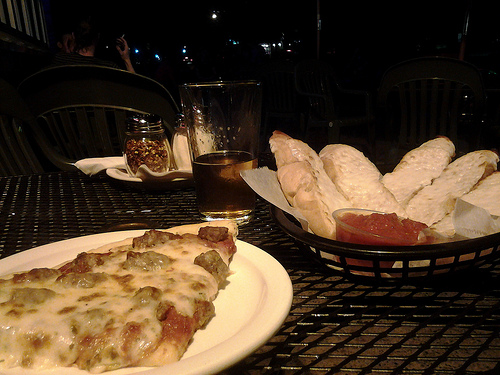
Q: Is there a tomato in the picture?
A: No, there are no tomatoes.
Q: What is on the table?
A: The spices are on the table.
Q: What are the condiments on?
A: The condiments are on the table.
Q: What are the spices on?
A: The condiments are on the table.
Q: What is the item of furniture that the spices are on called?
A: The piece of furniture is a table.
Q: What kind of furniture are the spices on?
A: The spices are on the table.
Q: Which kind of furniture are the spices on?
A: The spices are on the table.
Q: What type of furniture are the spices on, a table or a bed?
A: The spices are on a table.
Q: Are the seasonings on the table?
A: Yes, the seasonings are on the table.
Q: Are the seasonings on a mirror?
A: No, the seasonings are on the table.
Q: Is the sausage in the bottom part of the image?
A: Yes, the sausage is in the bottom of the image.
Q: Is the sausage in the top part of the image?
A: No, the sausage is in the bottom of the image.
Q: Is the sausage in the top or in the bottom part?
A: The sausage is in the bottom of the image.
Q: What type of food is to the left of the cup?
A: The food is a sausage.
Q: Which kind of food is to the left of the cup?
A: The food is a sausage.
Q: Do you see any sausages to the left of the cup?
A: Yes, there is a sausage to the left of the cup.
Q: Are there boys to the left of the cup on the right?
A: No, there is a sausage to the left of the cup.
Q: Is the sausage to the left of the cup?
A: Yes, the sausage is to the left of the cup.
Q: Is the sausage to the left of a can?
A: No, the sausage is to the left of the cup.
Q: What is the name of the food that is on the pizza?
A: The food is a sausage.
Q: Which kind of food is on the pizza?
A: The food is a sausage.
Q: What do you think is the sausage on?
A: The sausage is on the pizza.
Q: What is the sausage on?
A: The sausage is on the pizza.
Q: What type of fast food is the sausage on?
A: The sausage is on the pizza.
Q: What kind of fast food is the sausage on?
A: The sausage is on the pizza.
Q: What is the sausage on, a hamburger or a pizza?
A: The sausage is on a pizza.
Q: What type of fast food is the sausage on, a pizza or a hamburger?
A: The sausage is on a pizza.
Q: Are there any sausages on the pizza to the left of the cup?
A: Yes, there is a sausage on the pizza.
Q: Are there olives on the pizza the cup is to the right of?
A: No, there is a sausage on the pizza.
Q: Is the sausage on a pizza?
A: Yes, the sausage is on a pizza.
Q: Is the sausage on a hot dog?
A: No, the sausage is on a pizza.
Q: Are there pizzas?
A: Yes, there is a pizza.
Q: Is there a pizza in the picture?
A: Yes, there is a pizza.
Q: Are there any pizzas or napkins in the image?
A: Yes, there is a pizza.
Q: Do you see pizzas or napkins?
A: Yes, there is a pizza.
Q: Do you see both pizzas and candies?
A: No, there is a pizza but no candies.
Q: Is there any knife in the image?
A: No, there are no knives.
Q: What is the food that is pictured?
A: The food is a pizza.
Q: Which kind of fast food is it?
A: The food is a pizza.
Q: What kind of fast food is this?
A: This is a pizza.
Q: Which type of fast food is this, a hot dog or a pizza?
A: This is a pizza.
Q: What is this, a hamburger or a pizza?
A: This is a pizza.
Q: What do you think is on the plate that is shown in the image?
A: The pizza is on the plate.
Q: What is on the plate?
A: The pizza is on the plate.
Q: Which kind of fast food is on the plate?
A: The food is a pizza.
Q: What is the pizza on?
A: The pizza is on the plate.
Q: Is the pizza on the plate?
A: Yes, the pizza is on the plate.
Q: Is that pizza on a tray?
A: No, the pizza is on the plate.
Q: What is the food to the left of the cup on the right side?
A: The food is a pizza.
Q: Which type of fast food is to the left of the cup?
A: The food is a pizza.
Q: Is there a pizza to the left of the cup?
A: Yes, there is a pizza to the left of the cup.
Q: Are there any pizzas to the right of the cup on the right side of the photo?
A: No, the pizza is to the left of the cup.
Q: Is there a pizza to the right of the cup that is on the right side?
A: No, the pizza is to the left of the cup.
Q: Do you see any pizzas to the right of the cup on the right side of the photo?
A: No, the pizza is to the left of the cup.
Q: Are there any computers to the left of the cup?
A: No, there is a pizza to the left of the cup.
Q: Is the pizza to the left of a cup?
A: Yes, the pizza is to the left of a cup.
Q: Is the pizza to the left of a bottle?
A: No, the pizza is to the left of a cup.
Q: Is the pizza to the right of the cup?
A: No, the pizza is to the left of the cup.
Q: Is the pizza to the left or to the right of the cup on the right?
A: The pizza is to the left of the cup.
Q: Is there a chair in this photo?
A: Yes, there is a chair.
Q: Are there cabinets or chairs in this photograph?
A: Yes, there is a chair.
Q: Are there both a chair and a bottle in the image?
A: No, there is a chair but no bottles.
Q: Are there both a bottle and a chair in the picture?
A: No, there is a chair but no bottles.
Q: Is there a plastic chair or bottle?
A: Yes, there is a plastic chair.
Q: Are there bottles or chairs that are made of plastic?
A: Yes, the chair is made of plastic.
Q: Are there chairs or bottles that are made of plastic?
A: Yes, the chair is made of plastic.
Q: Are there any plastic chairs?
A: Yes, there is a chair that is made of plastic.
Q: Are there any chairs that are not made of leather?
A: Yes, there is a chair that is made of plastic.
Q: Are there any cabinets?
A: No, there are no cabinets.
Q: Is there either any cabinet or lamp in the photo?
A: No, there are no cabinets or lamps.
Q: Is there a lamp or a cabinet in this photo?
A: No, there are no cabinets or lamps.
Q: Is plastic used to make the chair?
A: Yes, the chair is made of plastic.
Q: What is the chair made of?
A: The chair is made of plastic.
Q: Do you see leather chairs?
A: No, there is a chair but it is made of plastic.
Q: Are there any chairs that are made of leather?
A: No, there is a chair but it is made of plastic.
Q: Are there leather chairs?
A: No, there is a chair but it is made of plastic.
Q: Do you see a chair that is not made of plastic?
A: No, there is a chair but it is made of plastic.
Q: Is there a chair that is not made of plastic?
A: No, there is a chair but it is made of plastic.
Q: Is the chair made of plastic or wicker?
A: The chair is made of plastic.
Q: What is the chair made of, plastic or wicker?
A: The chair is made of plastic.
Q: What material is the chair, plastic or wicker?
A: The chair is made of plastic.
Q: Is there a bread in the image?
A: Yes, there is a bread.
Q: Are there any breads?
A: Yes, there is a bread.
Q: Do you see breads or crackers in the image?
A: Yes, there is a bread.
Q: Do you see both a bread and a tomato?
A: No, there is a bread but no tomatoes.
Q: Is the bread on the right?
A: Yes, the bread is on the right of the image.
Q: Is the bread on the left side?
A: No, the bread is on the right of the image.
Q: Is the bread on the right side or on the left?
A: The bread is on the right of the image.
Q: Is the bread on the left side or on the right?
A: The bread is on the right of the image.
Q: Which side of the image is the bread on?
A: The bread is on the right of the image.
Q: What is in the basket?
A: The bread is in the basket.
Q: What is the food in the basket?
A: The food is a bread.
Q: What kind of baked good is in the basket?
A: The food is a bread.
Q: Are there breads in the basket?
A: Yes, there is a bread in the basket.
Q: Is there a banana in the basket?
A: No, there is a bread in the basket.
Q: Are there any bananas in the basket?
A: No, there is a bread in the basket.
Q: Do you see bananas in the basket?
A: No, there is a bread in the basket.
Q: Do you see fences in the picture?
A: No, there are no fences.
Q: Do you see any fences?
A: No, there are no fences.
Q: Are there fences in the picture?
A: No, there are no fences.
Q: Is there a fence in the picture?
A: No, there are no fences.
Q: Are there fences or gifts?
A: No, there are no fences or gifts.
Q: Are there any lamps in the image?
A: No, there are no lamps.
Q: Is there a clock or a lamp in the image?
A: No, there are no lamps or clocks.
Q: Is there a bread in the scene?
A: Yes, there is a bread.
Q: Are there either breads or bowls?
A: Yes, there is a bread.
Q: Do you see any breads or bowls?
A: Yes, there is a bread.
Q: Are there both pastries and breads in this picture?
A: No, there is a bread but no pastries.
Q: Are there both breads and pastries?
A: No, there is a bread but no pastries.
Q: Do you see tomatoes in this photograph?
A: No, there are no tomatoes.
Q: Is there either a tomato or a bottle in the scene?
A: No, there are no tomatoes or bottles.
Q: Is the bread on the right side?
A: Yes, the bread is on the right of the image.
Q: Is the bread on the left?
A: No, the bread is on the right of the image.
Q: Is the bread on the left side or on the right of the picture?
A: The bread is on the right of the image.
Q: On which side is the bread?
A: The bread is on the right of the image.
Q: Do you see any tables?
A: Yes, there is a table.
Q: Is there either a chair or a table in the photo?
A: Yes, there is a table.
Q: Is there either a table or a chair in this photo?
A: Yes, there is a table.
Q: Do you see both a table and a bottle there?
A: No, there is a table but no bottles.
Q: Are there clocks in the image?
A: No, there are no clocks.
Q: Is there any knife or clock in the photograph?
A: No, there are no clocks or knives.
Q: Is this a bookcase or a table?
A: This is a table.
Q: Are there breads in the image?
A: Yes, there is a bread.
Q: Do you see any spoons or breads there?
A: Yes, there is a bread.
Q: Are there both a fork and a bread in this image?
A: No, there is a bread but no forks.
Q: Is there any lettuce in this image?
A: No, there is no lettuce.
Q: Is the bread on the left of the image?
A: No, the bread is on the right of the image.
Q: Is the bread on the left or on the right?
A: The bread is on the right of the image.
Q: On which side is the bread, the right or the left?
A: The bread is on the right of the image.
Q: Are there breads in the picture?
A: Yes, there is a bread.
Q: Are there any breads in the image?
A: Yes, there is a bread.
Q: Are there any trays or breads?
A: Yes, there is a bread.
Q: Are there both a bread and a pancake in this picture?
A: No, there is a bread but no pancakes.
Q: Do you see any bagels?
A: No, there are no bagels.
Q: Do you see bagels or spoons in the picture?
A: No, there are no bagels or spoons.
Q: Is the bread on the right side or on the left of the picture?
A: The bread is on the right of the image.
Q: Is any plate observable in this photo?
A: Yes, there is a plate.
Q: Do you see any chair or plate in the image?
A: Yes, there is a plate.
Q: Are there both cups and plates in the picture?
A: Yes, there are both a plate and a cup.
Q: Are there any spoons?
A: No, there are no spoons.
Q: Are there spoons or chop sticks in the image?
A: No, there are no spoons or chop sticks.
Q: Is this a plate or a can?
A: This is a plate.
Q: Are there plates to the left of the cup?
A: Yes, there is a plate to the left of the cup.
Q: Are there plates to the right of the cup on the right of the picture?
A: No, the plate is to the left of the cup.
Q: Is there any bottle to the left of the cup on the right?
A: No, there is a plate to the left of the cup.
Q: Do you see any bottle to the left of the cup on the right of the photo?
A: No, there is a plate to the left of the cup.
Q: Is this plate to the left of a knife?
A: No, the plate is to the left of a cup.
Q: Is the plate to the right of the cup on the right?
A: No, the plate is to the left of the cup.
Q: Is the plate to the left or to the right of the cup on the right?
A: The plate is to the left of the cup.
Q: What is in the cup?
A: The sauce is in the cup.